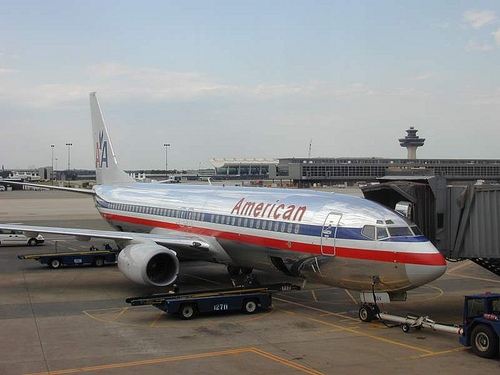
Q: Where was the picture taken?
A: It was taken at the airport.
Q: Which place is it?
A: It is an airport.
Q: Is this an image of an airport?
A: Yes, it is showing an airport.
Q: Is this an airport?
A: Yes, it is an airport.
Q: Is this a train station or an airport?
A: It is an airport.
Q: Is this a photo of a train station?
A: No, the picture is showing an airport.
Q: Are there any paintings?
A: No, there are no paintings.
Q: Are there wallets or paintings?
A: No, there are no paintings or wallets.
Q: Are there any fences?
A: No, there are no fences.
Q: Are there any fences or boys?
A: No, there are no fences or boys.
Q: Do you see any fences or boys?
A: No, there are no fences or boys.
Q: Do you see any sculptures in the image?
A: No, there are no sculptures.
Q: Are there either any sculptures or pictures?
A: No, there are no sculptures or pictures.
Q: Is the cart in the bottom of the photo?
A: Yes, the cart is in the bottom of the image.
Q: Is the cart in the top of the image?
A: No, the cart is in the bottom of the image.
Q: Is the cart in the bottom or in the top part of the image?
A: The cart is in the bottom of the image.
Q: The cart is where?
A: The cart is on the pavement.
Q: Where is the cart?
A: The cart is on the pavement.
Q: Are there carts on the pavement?
A: Yes, there is a cart on the pavement.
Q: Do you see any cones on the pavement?
A: No, there is a cart on the pavement.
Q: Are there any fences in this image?
A: No, there are no fences.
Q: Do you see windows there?
A: Yes, there are windows.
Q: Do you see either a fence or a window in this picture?
A: Yes, there are windows.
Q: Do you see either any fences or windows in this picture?
A: Yes, there are windows.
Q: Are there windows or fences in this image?
A: Yes, there are windows.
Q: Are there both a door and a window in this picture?
A: Yes, there are both a window and a door.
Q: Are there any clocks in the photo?
A: No, there are no clocks.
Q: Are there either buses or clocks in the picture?
A: No, there are no clocks or buses.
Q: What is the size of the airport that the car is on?
A: The airport is large.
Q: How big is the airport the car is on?
A: The airport is large.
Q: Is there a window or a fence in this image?
A: Yes, there are windows.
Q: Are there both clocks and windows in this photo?
A: No, there are windows but no clocks.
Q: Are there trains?
A: No, there are no trains.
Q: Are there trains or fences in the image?
A: No, there are no trains or fences.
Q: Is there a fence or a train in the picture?
A: No, there are no trains or fences.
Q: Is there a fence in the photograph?
A: No, there are no fences.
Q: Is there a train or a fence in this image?
A: No, there are no fences or trains.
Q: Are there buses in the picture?
A: No, there are no buses.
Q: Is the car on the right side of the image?
A: No, the car is on the left of the image.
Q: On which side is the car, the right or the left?
A: The car is on the left of the image.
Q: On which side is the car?
A: The car is on the left of the image.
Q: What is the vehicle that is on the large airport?
A: The vehicle is a car.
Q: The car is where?
A: The car is on the airport.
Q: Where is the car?
A: The car is on the airport.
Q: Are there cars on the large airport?
A: Yes, there is a car on the airport.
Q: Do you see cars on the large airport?
A: Yes, there is a car on the airport.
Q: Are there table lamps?
A: No, there are no table lamps.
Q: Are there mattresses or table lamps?
A: No, there are no table lamps or mattresses.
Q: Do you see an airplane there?
A: Yes, there is an airplane.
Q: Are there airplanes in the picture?
A: Yes, there is an airplane.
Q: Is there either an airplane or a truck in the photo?
A: Yes, there is an airplane.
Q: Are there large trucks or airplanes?
A: Yes, there is a large airplane.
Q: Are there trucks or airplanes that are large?
A: Yes, the airplane is large.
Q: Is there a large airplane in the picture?
A: Yes, there is a large airplane.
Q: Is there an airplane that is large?
A: Yes, there is an airplane that is large.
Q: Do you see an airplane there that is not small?
A: Yes, there is a large airplane.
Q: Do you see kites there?
A: No, there are no kites.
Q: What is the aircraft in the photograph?
A: The aircraft is an airplane.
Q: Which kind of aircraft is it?
A: The aircraft is an airplane.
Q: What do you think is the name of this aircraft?
A: That is an airplane.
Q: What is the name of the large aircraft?
A: The aircraft is an airplane.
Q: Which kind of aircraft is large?
A: The aircraft is an airplane.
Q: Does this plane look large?
A: Yes, the plane is large.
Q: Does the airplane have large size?
A: Yes, the airplane is large.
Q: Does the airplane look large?
A: Yes, the airplane is large.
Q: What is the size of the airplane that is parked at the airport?
A: The plane is large.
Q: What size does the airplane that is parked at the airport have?
A: The plane has large size.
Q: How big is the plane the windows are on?
A: The plane is large.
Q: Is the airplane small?
A: No, the airplane is large.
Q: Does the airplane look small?
A: No, the airplane is large.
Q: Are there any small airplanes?
A: No, there is an airplane but it is large.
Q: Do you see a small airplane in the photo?
A: No, there is an airplane but it is large.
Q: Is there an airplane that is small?
A: No, there is an airplane but it is large.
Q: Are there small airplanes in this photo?
A: No, there is an airplane but it is large.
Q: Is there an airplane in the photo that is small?
A: No, there is an airplane but it is large.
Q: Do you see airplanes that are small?
A: No, there is an airplane but it is large.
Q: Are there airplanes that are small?
A: No, there is an airplane but it is large.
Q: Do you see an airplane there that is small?
A: No, there is an airplane but it is large.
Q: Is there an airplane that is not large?
A: No, there is an airplane but it is large.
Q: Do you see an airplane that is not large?
A: No, there is an airplane but it is large.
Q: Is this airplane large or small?
A: The airplane is large.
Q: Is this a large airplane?
A: Yes, this is a large airplane.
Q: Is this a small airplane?
A: No, this is a large airplane.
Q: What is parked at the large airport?
A: The airplane is parked at the airport.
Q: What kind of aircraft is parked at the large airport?
A: The aircraft is an airplane.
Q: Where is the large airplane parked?
A: The airplane is parked at the airport.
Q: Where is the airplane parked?
A: The airplane is parked at the airport.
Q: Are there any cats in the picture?
A: No, there are no cats.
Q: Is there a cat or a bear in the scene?
A: No, there are no cats or bears.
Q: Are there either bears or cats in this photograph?
A: No, there are no cats or bears.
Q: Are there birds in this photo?
A: No, there are no birds.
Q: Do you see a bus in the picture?
A: No, there are no buses.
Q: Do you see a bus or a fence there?
A: No, there are no buses or fences.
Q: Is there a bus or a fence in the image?
A: No, there are no buses or fences.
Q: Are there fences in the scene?
A: No, there are no fences.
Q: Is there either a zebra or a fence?
A: No, there are no fences or zebras.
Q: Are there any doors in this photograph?
A: Yes, there is a door.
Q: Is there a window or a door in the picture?
A: Yes, there is a door.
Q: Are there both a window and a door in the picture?
A: Yes, there are both a door and a window.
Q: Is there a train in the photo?
A: No, there are no trains.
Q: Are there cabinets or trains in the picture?
A: No, there are no trains or cabinets.